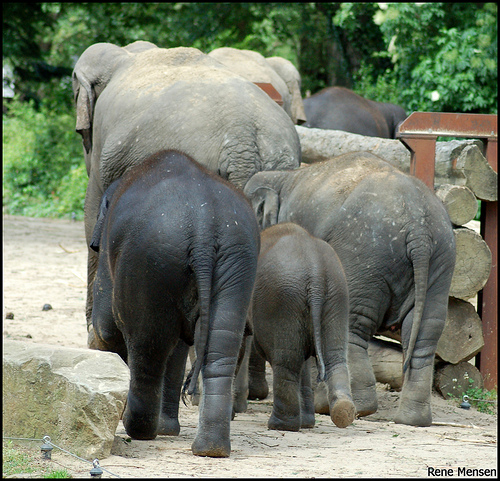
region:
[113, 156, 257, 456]
the elephant is black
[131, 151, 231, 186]
hair is on the back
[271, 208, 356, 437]
the elephant is the smallest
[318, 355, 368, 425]
oneleg is in the air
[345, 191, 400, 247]
white paint is on the elephant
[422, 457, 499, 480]
the photographer is rene mensen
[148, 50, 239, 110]
light is on the elephant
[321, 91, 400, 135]
the elephant is black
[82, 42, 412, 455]
the elephants are six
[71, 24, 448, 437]
the elephants are social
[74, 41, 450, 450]
backs of walking elephants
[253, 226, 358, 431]
rear end of baby elephant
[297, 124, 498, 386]
stack of logs in rack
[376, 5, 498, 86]
green leaves on branch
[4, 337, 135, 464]
rock with flat top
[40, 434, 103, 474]
wire in metal hooks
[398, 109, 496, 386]
rusted red metal rack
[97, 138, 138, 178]
wrinkled skin on elephant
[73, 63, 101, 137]
folded ear on head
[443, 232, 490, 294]
end of cut log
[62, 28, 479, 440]
five elephants walking away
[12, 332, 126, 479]
rock needs to elephants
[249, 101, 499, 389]
five logs stacked together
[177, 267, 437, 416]
three tails of smaller elephants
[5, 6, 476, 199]
foliage in the background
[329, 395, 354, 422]
bottom of smallest elephants foot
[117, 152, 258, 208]
dark spots on elephant's back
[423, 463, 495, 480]
black text on photo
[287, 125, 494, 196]
top log in stack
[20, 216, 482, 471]
dirt elephants are walking on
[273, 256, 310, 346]
gray rump of elephant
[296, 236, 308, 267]
elephant is a baby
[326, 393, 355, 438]
small gray elephant foot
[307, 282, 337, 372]
short gray elephants tail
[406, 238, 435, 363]
long dusty elephant tail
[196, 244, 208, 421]
long gray elephants tail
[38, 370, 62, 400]
large rock by elephant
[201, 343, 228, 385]
big wrinkle on elephants knee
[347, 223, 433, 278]
white spots on elephants rump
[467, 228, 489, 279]
wooden log by elephant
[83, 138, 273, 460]
the back left elephants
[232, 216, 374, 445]
the smallest elephant near the center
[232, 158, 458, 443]
the small right elephant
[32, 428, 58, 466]
a metal anchor on the ground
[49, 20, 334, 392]
a large elephant leading the small ones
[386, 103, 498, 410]
a metal contailer holding wood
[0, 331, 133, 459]
a large gray rock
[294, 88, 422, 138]
the back of an elephant far away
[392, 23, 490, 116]
some foliage above the elephants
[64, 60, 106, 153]
the large elephants ear